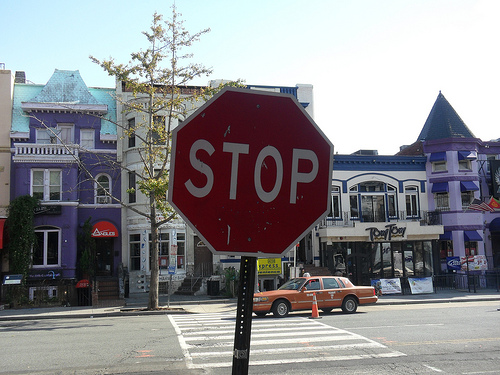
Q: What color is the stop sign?
A: Red.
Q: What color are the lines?
A: White.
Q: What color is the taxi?
A: Orange.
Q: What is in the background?
A: Storefronts.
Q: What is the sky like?
A: Clear.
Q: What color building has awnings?
A: Purple.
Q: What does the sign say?
A: Stop.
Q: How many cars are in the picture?
A: One.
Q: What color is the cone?
A: Orange.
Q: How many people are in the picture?
A: None.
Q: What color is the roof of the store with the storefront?
A: Blue.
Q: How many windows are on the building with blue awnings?
A: Six.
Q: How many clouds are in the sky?
A: Zero.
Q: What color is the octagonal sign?
A: Red.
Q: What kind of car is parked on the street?
A: A taxi.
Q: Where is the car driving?
A: In the crosswalk.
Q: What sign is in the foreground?
A: Stop.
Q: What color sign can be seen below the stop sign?
A: Yellow.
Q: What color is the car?
A: Orange.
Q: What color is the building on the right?
A: Purple.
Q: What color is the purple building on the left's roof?
A: Blue.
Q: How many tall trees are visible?
A: One.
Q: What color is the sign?
A: Red and white.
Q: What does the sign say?
A: Stop.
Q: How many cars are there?
A: One.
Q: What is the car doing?
A: Driving.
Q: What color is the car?
A: Orange.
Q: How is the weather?
A: Sunny.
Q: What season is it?
A: Spring.